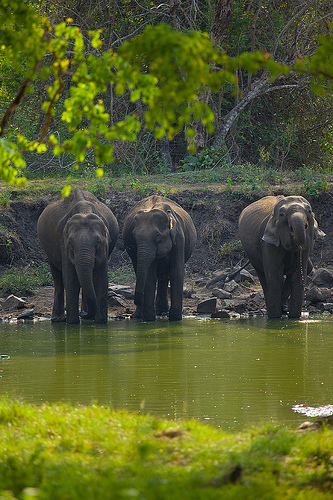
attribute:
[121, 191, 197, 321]
elephant — walking, drinking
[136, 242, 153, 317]
trunk — wet, drinking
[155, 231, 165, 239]
eye — black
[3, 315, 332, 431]
water — green, calm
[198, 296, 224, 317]
rock — gray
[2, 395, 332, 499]
grass — green, the grass